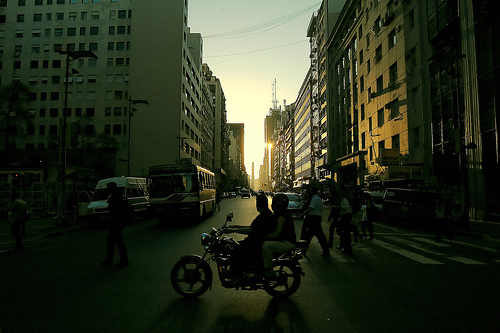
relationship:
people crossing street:
[295, 183, 376, 253] [138, 232, 201, 251]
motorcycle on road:
[173, 227, 306, 312] [126, 300, 247, 331]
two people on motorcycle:
[237, 196, 305, 250] [169, 227, 306, 299]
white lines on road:
[382, 233, 476, 277] [126, 300, 247, 331]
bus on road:
[142, 167, 221, 224] [126, 300, 247, 331]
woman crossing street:
[362, 190, 381, 241] [138, 232, 201, 251]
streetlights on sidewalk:
[59, 45, 143, 167] [45, 216, 52, 229]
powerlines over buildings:
[207, 10, 308, 34] [289, 23, 465, 99]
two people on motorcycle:
[237, 196, 305, 250] [173, 227, 306, 312]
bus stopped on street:
[142, 167, 221, 224] [138, 232, 201, 251]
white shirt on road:
[301, 194, 331, 218] [126, 300, 247, 331]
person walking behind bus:
[214, 185, 226, 212] [142, 167, 221, 224]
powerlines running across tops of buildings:
[207, 10, 308, 34] [182, 0, 329, 26]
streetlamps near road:
[123, 95, 147, 175] [126, 300, 247, 331]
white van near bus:
[124, 177, 150, 214] [142, 167, 221, 224]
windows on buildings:
[328, 70, 375, 107] [289, 23, 465, 99]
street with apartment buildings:
[138, 232, 201, 251] [270, 126, 303, 190]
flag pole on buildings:
[278, 92, 291, 107] [269, 116, 282, 164]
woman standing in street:
[362, 190, 381, 241] [138, 232, 201, 251]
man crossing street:
[9, 178, 38, 268] [138, 232, 201, 251]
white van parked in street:
[87, 177, 150, 213] [138, 232, 201, 251]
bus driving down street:
[142, 167, 221, 224] [138, 232, 201, 251]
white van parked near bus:
[124, 177, 150, 214] [142, 167, 221, 224]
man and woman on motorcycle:
[250, 194, 292, 222] [173, 227, 306, 312]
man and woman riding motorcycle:
[220, 194, 292, 282] [173, 227, 306, 312]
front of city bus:
[146, 165, 211, 216] [142, 167, 221, 224]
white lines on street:
[382, 233, 476, 277] [138, 232, 201, 251]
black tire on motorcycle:
[173, 259, 211, 304] [173, 227, 306, 312]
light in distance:
[237, 146, 267, 190] [244, 149, 272, 161]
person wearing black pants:
[305, 182, 323, 260] [308, 217, 326, 247]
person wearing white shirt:
[305, 182, 323, 260] [307, 194, 322, 218]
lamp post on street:
[437, 52, 475, 229] [138, 232, 201, 251]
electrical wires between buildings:
[171, 3, 331, 29] [117, 16, 368, 83]